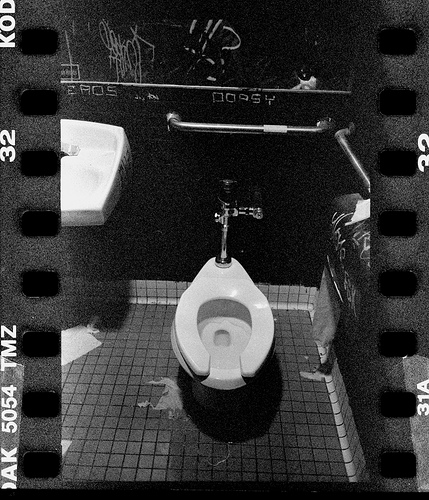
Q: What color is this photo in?
A: Black and white.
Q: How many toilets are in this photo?
A: 1.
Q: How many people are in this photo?
A: 0.